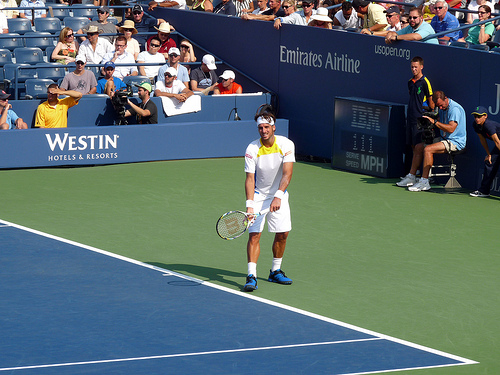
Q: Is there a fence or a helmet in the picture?
A: No, there are no fences or helmets.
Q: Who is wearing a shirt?
A: The man is wearing a shirt.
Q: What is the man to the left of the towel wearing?
A: The man is wearing a shirt.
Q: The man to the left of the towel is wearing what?
A: The man is wearing a shirt.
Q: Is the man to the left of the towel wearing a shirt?
A: Yes, the man is wearing a shirt.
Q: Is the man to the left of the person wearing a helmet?
A: No, the man is wearing a shirt.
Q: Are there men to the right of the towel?
A: No, the man is to the left of the towel.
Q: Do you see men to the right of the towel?
A: No, the man is to the left of the towel.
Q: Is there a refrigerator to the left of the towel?
A: No, there is a man to the left of the towel.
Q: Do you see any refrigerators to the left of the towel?
A: No, there is a man to the left of the towel.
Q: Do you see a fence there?
A: No, there are no fences.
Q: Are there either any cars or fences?
A: No, there are no fences or cars.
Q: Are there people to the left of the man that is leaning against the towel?
A: Yes, there is a person to the left of the man.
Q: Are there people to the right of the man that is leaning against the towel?
A: No, the person is to the left of the man.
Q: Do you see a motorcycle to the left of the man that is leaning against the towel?
A: No, there is a person to the left of the man.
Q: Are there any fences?
A: No, there are no fences.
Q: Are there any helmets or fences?
A: No, there are no fences or helmets.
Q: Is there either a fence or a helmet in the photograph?
A: No, there are no fences or helmets.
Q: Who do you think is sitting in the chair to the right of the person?
A: The man is sitting in the chair.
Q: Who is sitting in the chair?
A: The man is sitting in the chair.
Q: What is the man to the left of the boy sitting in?
A: The man is sitting in the chair.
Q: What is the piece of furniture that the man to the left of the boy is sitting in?
A: The piece of furniture is a chair.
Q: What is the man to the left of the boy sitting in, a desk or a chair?
A: The man is sitting in a chair.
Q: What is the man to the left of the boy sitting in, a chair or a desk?
A: The man is sitting in a chair.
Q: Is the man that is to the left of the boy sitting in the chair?
A: Yes, the man is sitting in the chair.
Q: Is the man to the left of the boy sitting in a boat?
A: No, the man is sitting in the chair.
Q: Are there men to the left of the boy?
A: Yes, there is a man to the left of the boy.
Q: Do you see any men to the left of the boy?
A: Yes, there is a man to the left of the boy.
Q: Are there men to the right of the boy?
A: No, the man is to the left of the boy.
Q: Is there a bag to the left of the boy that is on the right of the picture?
A: No, there is a man to the left of the boy.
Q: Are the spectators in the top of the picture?
A: Yes, the spectators are in the top of the image.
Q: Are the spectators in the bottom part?
A: No, the spectators are in the top of the image.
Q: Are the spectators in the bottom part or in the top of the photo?
A: The spectators are in the top of the image.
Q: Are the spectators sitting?
A: Yes, the spectators are sitting.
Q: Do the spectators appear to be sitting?
A: Yes, the spectators are sitting.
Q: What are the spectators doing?
A: The spectators are sitting.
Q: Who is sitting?
A: The spectators are sitting.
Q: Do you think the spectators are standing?
A: No, the spectators are sitting.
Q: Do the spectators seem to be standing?
A: No, the spectators are sitting.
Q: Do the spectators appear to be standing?
A: No, the spectators are sitting.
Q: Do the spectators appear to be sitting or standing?
A: The spectators are sitting.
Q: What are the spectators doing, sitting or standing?
A: The spectators are sitting.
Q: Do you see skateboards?
A: No, there are no skateboards.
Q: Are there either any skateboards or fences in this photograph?
A: No, there are no skateboards or fences.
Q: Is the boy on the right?
A: Yes, the boy is on the right of the image.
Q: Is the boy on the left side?
A: No, the boy is on the right of the image.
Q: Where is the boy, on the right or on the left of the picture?
A: The boy is on the right of the image.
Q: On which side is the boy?
A: The boy is on the right of the image.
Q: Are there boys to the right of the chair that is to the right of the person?
A: Yes, there is a boy to the right of the chair.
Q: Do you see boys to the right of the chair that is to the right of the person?
A: Yes, there is a boy to the right of the chair.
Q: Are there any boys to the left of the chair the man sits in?
A: No, the boy is to the right of the chair.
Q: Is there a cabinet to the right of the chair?
A: No, there is a boy to the right of the chair.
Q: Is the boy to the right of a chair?
A: Yes, the boy is to the right of a chair.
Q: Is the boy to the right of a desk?
A: No, the boy is to the right of a chair.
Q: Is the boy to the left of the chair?
A: No, the boy is to the right of the chair.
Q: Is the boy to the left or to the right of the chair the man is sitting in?
A: The boy is to the right of the chair.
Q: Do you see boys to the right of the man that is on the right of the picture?
A: Yes, there is a boy to the right of the man.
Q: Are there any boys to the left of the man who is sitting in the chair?
A: No, the boy is to the right of the man.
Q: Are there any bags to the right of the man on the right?
A: No, there is a boy to the right of the man.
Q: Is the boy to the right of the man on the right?
A: Yes, the boy is to the right of the man.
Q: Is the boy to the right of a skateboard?
A: No, the boy is to the right of the man.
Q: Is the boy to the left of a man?
A: No, the boy is to the right of a man.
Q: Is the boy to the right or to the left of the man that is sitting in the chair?
A: The boy is to the right of the man.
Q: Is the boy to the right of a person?
A: Yes, the boy is to the right of a person.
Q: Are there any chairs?
A: Yes, there is a chair.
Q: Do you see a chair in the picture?
A: Yes, there is a chair.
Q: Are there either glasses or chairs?
A: Yes, there is a chair.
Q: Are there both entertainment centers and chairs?
A: No, there is a chair but no entertainment centers.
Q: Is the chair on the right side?
A: Yes, the chair is on the right of the image.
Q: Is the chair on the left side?
A: No, the chair is on the right of the image.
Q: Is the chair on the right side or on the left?
A: The chair is on the right of the image.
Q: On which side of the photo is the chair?
A: The chair is on the right of the image.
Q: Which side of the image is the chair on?
A: The chair is on the right of the image.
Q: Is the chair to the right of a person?
A: Yes, the chair is to the right of a person.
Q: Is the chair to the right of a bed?
A: No, the chair is to the right of a person.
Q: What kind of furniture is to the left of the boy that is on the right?
A: The piece of furniture is a chair.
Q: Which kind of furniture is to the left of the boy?
A: The piece of furniture is a chair.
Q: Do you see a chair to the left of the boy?
A: Yes, there is a chair to the left of the boy.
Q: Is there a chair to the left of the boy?
A: Yes, there is a chair to the left of the boy.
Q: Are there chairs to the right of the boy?
A: No, the chair is to the left of the boy.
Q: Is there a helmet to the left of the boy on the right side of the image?
A: No, there is a chair to the left of the boy.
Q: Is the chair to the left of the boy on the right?
A: Yes, the chair is to the left of the boy.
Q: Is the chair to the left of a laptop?
A: No, the chair is to the left of the boy.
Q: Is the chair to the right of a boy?
A: No, the chair is to the left of a boy.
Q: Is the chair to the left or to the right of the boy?
A: The chair is to the left of the boy.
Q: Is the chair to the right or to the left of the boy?
A: The chair is to the left of the boy.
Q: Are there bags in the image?
A: No, there are no bags.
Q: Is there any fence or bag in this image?
A: No, there are no bags or fences.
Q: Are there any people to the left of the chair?
A: Yes, there is a person to the left of the chair.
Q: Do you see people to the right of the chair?
A: No, the person is to the left of the chair.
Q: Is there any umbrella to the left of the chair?
A: No, there is a person to the left of the chair.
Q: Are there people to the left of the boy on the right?
A: Yes, there is a person to the left of the boy.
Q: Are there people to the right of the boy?
A: No, the person is to the left of the boy.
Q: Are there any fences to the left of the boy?
A: No, there is a person to the left of the boy.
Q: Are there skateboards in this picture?
A: No, there are no skateboards.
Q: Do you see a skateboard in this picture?
A: No, there are no skateboards.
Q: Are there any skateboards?
A: No, there are no skateboards.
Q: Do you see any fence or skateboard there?
A: No, there are no skateboards or fences.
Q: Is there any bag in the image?
A: No, there are no bags.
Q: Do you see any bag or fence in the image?
A: No, there are no bags or fences.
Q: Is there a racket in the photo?
A: Yes, there is a racket.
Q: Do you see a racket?
A: Yes, there is a racket.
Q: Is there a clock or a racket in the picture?
A: Yes, there is a racket.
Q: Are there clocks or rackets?
A: Yes, there is a racket.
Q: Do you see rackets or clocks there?
A: Yes, there is a racket.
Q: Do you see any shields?
A: No, there are no shields.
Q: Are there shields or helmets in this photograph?
A: No, there are no shields or helmets.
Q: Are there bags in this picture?
A: No, there are no bags.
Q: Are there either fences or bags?
A: No, there are no bags or fences.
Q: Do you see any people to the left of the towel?
A: Yes, there is a person to the left of the towel.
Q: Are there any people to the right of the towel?
A: No, the person is to the left of the towel.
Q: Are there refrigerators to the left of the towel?
A: No, there is a person to the left of the towel.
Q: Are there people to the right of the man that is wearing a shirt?
A: Yes, there is a person to the right of the man.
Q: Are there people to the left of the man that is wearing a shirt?
A: No, the person is to the right of the man.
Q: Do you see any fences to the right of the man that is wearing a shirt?
A: No, there is a person to the right of the man.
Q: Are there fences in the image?
A: No, there are no fences.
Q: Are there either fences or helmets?
A: No, there are no fences or helmets.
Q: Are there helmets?
A: No, there are no helmets.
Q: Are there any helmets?
A: No, there are no helmets.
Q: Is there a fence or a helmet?
A: No, there are no helmets or fences.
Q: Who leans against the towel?
A: The man leans against the towel.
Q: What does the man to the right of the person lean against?
A: The man leans against the towel.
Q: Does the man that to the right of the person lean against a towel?
A: Yes, the man leans against a towel.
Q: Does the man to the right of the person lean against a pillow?
A: No, the man leans against a towel.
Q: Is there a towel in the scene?
A: Yes, there is a towel.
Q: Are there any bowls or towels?
A: Yes, there is a towel.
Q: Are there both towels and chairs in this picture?
A: Yes, there are both a towel and a chair.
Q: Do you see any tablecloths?
A: No, there are no tablecloths.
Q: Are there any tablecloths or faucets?
A: No, there are no tablecloths or faucets.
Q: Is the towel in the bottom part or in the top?
A: The towel is in the top of the image.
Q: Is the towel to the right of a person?
A: Yes, the towel is to the right of a person.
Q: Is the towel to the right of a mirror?
A: No, the towel is to the right of a person.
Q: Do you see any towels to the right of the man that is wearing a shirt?
A: Yes, there is a towel to the right of the man.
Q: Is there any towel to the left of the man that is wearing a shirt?
A: No, the towel is to the right of the man.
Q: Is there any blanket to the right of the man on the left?
A: No, there is a towel to the right of the man.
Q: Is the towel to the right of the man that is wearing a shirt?
A: Yes, the towel is to the right of the man.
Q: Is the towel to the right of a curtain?
A: No, the towel is to the right of the man.